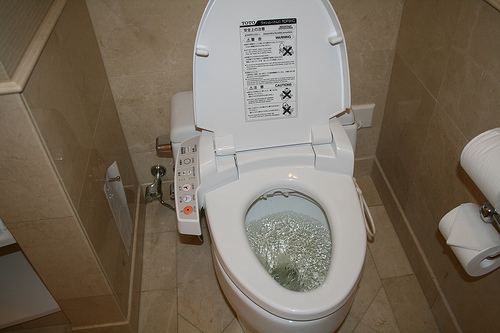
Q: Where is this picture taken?
A: A bathroom.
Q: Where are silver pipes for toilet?
A: On left side of toilet.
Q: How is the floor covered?
A: In tiles.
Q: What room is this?
A: Bathroom.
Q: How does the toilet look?
A: Dirty.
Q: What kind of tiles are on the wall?
A: Brown ceramic.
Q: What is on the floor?
A: Brown ceramic tiles.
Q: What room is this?
A: Bathroom.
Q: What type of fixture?
A: Toilet.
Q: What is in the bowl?
A: Water.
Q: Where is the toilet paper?
A: On the wall.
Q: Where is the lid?
A: Up.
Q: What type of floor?
A: Tile.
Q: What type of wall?
A: Tile.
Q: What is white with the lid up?
A: Toilet.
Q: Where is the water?
A: In the bowl.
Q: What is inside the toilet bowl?
A: Water.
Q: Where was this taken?
A: In a bathroom.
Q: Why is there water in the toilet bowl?
A: To facilitate the disposal of waste.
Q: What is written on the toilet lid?
A: Instructions.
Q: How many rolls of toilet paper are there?
A: Two.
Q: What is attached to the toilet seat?
A: A control panel.